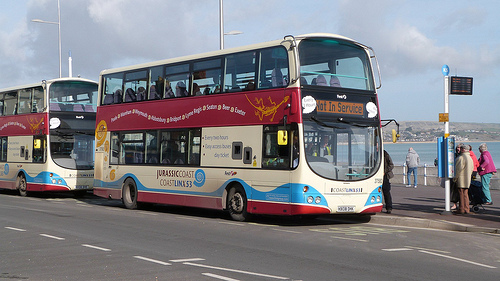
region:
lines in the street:
[142, 248, 220, 269]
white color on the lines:
[35, 224, 162, 271]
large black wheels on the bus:
[215, 177, 264, 225]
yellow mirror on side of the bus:
[277, 124, 294, 151]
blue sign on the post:
[430, 132, 456, 184]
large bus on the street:
[95, 32, 408, 251]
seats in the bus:
[305, 64, 355, 86]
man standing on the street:
[444, 139, 477, 205]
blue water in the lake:
[405, 138, 438, 154]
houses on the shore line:
[403, 121, 441, 141]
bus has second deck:
[111, 40, 388, 240]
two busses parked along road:
[11, 70, 370, 205]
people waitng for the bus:
[438, 146, 498, 210]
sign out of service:
[317, 100, 375, 125]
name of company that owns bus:
[146, 165, 200, 197]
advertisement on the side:
[198, 132, 258, 168]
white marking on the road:
[16, 212, 206, 274]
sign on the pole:
[431, 74, 484, 100]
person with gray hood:
[403, 146, 431, 195]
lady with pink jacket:
[471, 151, 496, 177]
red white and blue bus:
[110, 51, 342, 239]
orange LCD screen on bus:
[308, 96, 360, 117]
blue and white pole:
[396, 80, 457, 220]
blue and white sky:
[399, 4, 467, 113]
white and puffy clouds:
[365, 2, 450, 81]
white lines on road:
[20, 207, 265, 279]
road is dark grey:
[22, 215, 270, 278]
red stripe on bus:
[99, 88, 284, 131]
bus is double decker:
[84, 47, 412, 232]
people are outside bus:
[396, 146, 478, 200]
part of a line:
[141, 251, 146, 263]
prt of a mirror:
[368, 117, 435, 159]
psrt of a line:
[63, 214, 130, 271]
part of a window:
[320, 120, 396, 180]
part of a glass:
[327, 125, 354, 158]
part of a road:
[77, 201, 122, 241]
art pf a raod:
[90, 218, 102, 232]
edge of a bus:
[284, 170, 301, 195]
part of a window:
[335, 114, 368, 157]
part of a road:
[88, 209, 118, 236]